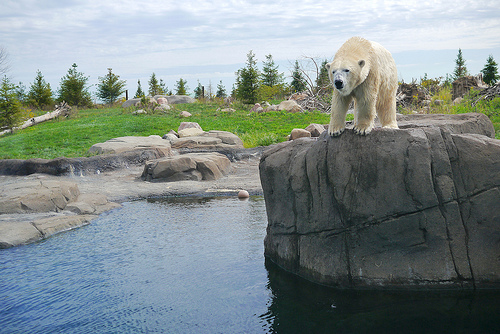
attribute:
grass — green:
[0, 87, 498, 159]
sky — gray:
[5, 8, 490, 78]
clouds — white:
[25, 6, 469, 65]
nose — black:
[333, 77, 345, 91]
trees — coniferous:
[2, 48, 323, 113]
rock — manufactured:
[281, 149, 338, 223]